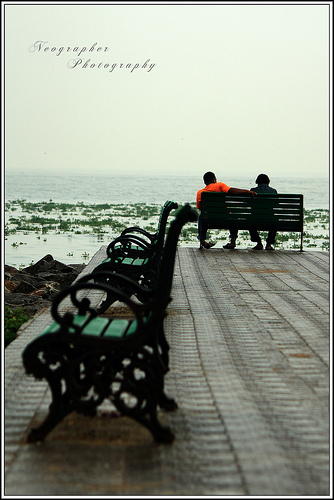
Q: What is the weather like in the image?
A: It is overcast.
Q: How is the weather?
A: It is overcast.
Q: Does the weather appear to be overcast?
A: Yes, it is overcast.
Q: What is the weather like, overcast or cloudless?
A: It is overcast.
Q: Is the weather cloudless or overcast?
A: It is overcast.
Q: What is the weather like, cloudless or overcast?
A: It is overcast.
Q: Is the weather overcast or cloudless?
A: It is overcast.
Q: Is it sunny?
A: No, it is overcast.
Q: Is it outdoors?
A: Yes, it is outdoors.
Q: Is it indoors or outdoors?
A: It is outdoors.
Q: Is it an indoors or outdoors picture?
A: It is outdoors.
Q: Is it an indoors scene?
A: No, it is outdoors.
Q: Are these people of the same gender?
A: No, they are both male and female.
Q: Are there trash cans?
A: No, there are no trash cans.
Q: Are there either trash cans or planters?
A: No, there are no trash cans or planters.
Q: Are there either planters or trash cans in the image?
A: No, there are no trash cans or planters.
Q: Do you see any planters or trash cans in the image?
A: No, there are no trash cans or planters.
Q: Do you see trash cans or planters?
A: No, there are no trash cans or planters.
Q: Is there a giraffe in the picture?
A: No, there are no giraffes.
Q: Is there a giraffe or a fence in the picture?
A: No, there are no giraffes or fences.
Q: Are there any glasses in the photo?
A: No, there are no glasses.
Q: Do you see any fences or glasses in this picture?
A: No, there are no glasses or fences.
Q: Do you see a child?
A: No, there are no children.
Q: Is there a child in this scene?
A: No, there are no children.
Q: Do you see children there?
A: No, there are no children.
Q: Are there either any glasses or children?
A: No, there are no children or glasses.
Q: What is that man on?
A: The man is on the bench.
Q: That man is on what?
A: The man is on the bench.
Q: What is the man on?
A: The man is on the bench.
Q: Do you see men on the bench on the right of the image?
A: Yes, there is a man on the bench.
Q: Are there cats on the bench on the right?
A: No, there is a man on the bench.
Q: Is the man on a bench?
A: Yes, the man is on a bench.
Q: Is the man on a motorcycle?
A: No, the man is on a bench.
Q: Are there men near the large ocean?
A: Yes, there is a man near the ocean.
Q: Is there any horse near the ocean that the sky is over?
A: No, there is a man near the ocean.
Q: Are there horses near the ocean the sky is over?
A: No, there is a man near the ocean.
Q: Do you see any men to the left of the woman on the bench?
A: Yes, there is a man to the left of the woman.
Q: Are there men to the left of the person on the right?
A: Yes, there is a man to the left of the woman.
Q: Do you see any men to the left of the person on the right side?
A: Yes, there is a man to the left of the woman.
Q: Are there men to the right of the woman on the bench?
A: No, the man is to the left of the woman.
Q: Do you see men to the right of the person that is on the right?
A: No, the man is to the left of the woman.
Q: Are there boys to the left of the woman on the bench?
A: No, there is a man to the left of the woman.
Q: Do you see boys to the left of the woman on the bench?
A: No, there is a man to the left of the woman.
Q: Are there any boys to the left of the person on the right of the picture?
A: No, there is a man to the left of the woman.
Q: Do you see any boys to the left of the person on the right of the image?
A: No, there is a man to the left of the woman.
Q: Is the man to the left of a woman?
A: Yes, the man is to the left of a woman.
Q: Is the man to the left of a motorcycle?
A: No, the man is to the left of a woman.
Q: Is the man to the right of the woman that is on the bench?
A: No, the man is to the left of the woman.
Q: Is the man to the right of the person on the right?
A: No, the man is to the left of the woman.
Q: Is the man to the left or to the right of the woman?
A: The man is to the left of the woman.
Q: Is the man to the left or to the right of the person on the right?
A: The man is to the left of the woman.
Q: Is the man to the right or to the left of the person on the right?
A: The man is to the left of the woman.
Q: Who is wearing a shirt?
A: The man is wearing a shirt.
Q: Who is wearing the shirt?
A: The man is wearing a shirt.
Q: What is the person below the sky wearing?
A: The man is wearing a shirt.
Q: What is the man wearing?
A: The man is wearing a shirt.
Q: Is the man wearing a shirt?
A: Yes, the man is wearing a shirt.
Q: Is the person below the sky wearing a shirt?
A: Yes, the man is wearing a shirt.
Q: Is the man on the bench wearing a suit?
A: No, the man is wearing a shirt.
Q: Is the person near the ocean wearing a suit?
A: No, the man is wearing a shirt.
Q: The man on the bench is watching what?
A: The man is watching the ocean.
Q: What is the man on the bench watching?
A: The man is watching the ocean.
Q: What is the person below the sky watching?
A: The man is watching the ocean.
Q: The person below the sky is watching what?
A: The man is watching the ocean.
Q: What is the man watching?
A: The man is watching the ocean.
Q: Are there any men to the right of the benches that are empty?
A: Yes, there is a man to the right of the benches.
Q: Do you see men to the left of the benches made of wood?
A: No, the man is to the right of the benches.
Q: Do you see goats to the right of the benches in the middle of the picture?
A: No, there is a man to the right of the benches.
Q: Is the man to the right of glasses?
A: No, the man is to the right of the benches.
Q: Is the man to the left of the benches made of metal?
A: No, the man is to the right of the benches.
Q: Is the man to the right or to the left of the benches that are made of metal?
A: The man is to the right of the benches.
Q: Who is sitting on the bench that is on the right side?
A: The man is sitting on the bench.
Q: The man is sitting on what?
A: The man is sitting on the bench.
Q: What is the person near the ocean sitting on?
A: The man is sitting on the bench.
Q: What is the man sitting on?
A: The man is sitting on the bench.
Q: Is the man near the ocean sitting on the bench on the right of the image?
A: Yes, the man is sitting on the bench.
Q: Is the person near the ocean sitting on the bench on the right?
A: Yes, the man is sitting on the bench.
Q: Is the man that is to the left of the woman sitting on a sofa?
A: No, the man is sitting on the bench.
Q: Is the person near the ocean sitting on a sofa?
A: No, the man is sitting on the bench.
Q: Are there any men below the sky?
A: Yes, there is a man below the sky.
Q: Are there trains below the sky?
A: No, there is a man below the sky.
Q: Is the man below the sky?
A: Yes, the man is below the sky.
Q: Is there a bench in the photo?
A: Yes, there is a bench.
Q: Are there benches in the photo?
A: Yes, there is a bench.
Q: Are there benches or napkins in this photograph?
A: Yes, there is a bench.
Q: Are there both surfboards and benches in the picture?
A: No, there is a bench but no surfboards.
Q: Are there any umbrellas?
A: No, there are no umbrellas.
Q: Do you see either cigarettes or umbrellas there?
A: No, there are no umbrellas or cigarettes.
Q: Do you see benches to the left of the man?
A: Yes, there is a bench to the left of the man.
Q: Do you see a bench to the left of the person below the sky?
A: Yes, there is a bench to the left of the man.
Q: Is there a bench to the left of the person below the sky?
A: Yes, there is a bench to the left of the man.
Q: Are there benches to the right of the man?
A: No, the bench is to the left of the man.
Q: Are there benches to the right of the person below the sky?
A: No, the bench is to the left of the man.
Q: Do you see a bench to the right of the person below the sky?
A: No, the bench is to the left of the man.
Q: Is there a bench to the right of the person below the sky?
A: No, the bench is to the left of the man.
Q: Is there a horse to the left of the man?
A: No, there is a bench to the left of the man.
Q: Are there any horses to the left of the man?
A: No, there is a bench to the left of the man.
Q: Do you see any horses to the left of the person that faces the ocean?
A: No, there is a bench to the left of the man.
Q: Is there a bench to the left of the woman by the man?
A: Yes, there is a bench to the left of the woman.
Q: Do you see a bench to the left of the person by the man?
A: Yes, there is a bench to the left of the woman.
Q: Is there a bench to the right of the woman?
A: No, the bench is to the left of the woman.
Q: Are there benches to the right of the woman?
A: No, the bench is to the left of the woman.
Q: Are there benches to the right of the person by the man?
A: No, the bench is to the left of the woman.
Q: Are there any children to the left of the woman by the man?
A: No, there is a bench to the left of the woman.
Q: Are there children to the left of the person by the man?
A: No, there is a bench to the left of the woman.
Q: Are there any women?
A: Yes, there is a woman.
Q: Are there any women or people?
A: Yes, there is a woman.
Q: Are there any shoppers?
A: No, there are no shoppers.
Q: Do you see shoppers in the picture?
A: No, there are no shoppers.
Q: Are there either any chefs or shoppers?
A: No, there are no shoppers or chefs.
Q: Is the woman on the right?
A: Yes, the woman is on the right of the image.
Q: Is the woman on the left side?
A: No, the woman is on the right of the image.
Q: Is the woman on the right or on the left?
A: The woman is on the right of the image.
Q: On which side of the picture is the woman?
A: The woman is on the right of the image.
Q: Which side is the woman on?
A: The woman is on the right of the image.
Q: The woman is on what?
A: The woman is on the bench.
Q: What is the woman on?
A: The woman is on the bench.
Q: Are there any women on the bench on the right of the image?
A: Yes, there is a woman on the bench.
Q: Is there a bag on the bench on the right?
A: No, there is a woman on the bench.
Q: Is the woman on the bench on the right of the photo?
A: Yes, the woman is on the bench.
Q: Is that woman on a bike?
A: No, the woman is on the bench.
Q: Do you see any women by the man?
A: Yes, there is a woman by the man.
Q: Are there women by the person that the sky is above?
A: Yes, there is a woman by the man.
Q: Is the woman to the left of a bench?
A: No, the woman is to the right of a bench.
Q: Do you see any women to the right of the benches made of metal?
A: Yes, there is a woman to the right of the benches.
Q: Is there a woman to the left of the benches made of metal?
A: No, the woman is to the right of the benches.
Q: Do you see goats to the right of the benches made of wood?
A: No, there is a woman to the right of the benches.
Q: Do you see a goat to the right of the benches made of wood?
A: No, there is a woman to the right of the benches.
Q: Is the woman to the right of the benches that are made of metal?
A: Yes, the woman is to the right of the benches.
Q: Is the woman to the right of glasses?
A: No, the woman is to the right of the benches.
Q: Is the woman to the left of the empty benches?
A: No, the woman is to the right of the benches.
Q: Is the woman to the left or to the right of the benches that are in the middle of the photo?
A: The woman is to the right of the benches.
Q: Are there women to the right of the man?
A: Yes, there is a woman to the right of the man.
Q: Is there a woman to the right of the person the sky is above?
A: Yes, there is a woman to the right of the man.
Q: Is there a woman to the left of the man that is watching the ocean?
A: No, the woman is to the right of the man.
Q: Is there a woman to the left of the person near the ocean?
A: No, the woman is to the right of the man.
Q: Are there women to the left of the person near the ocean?
A: No, the woman is to the right of the man.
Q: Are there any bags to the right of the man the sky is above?
A: No, there is a woman to the right of the man.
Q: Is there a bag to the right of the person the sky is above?
A: No, there is a woman to the right of the man.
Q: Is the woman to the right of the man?
A: Yes, the woman is to the right of the man.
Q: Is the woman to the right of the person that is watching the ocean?
A: Yes, the woman is to the right of the man.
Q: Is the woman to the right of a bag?
A: No, the woman is to the right of the man.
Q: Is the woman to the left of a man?
A: No, the woman is to the right of a man.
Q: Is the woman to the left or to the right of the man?
A: The woman is to the right of the man.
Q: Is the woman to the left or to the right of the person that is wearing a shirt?
A: The woman is to the right of the man.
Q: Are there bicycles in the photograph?
A: No, there are no bicycles.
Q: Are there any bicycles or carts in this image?
A: No, there are no bicycles or carts.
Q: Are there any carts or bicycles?
A: No, there are no bicycles or carts.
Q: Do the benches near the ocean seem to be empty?
A: Yes, the benches are empty.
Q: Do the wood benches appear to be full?
A: No, the benches are empty.